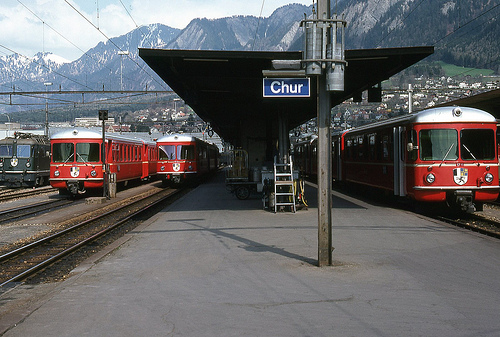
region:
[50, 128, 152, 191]
Red and white colored railroad train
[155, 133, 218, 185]
Red and white colored railroad train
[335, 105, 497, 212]
Red and white colored railroad train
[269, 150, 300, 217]
Small step ladder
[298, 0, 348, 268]
Electrical metal post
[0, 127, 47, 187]
Grey and green colored railroad train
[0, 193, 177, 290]
Railroad train tracks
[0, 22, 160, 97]
Mountain ranges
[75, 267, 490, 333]
Grey concrete pavement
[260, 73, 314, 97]
Blue Sign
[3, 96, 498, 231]
Four trains are in station.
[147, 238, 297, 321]
Pavement is grey color.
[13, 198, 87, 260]
Tracks are brown color.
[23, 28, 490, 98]
Mountains are behind the train.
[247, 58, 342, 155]
Board is attached to the pole.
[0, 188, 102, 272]
Gravel is brown color.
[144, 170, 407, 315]
Shadow falls on ground.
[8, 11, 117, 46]
Clouds are white color.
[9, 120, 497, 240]
Trains are on track.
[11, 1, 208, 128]
Power lines are passing above the train.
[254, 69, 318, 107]
A blue sign at the train station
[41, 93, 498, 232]
A front view of three trains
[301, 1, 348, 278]
A metal pole is in the foreground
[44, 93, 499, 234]
Three trains are bright red in color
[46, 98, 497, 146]
The top of the three trains are silver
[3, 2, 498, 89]
Mountains are in the background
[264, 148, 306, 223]
A silver colored ladder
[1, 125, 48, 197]
Train is dark green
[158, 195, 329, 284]
Metal pole is casting a shadow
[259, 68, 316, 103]
Blue sign says the word "Chur"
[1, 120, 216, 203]
three trains on train tracks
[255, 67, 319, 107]
blue and white sign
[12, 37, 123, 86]
snow on mountain top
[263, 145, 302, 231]
small grey metal ladder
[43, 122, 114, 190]
train with windshield wipers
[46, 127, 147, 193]
red train on tracks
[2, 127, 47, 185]
black train on tracks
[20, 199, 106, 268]
train tracks next to cement waiting area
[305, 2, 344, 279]
metal post with electric boxes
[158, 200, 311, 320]
shadow on the ground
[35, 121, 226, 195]
red trains on tracks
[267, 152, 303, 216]
ladder at a train station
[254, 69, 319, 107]
blue sign on train platform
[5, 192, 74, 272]
train tracks by platform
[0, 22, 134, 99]
mountains in the background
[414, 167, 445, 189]
front light of a train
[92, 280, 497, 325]
ground of a train platform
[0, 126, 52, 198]
black train on the end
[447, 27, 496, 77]
trees along side a hill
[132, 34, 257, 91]
roof of a train platform